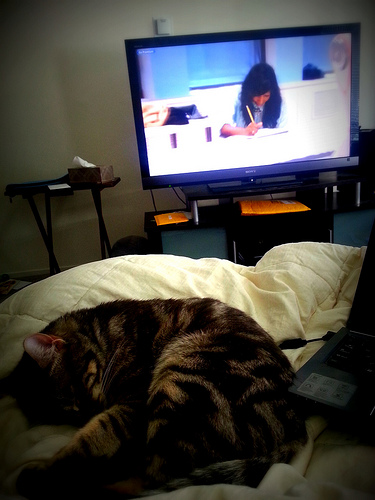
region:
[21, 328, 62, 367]
the ear of a cat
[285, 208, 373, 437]
a laptop on a bed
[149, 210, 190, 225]
an orange package on a table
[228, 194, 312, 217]
an orange package on a table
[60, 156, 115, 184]
a box of napkins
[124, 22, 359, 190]
a large black television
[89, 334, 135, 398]
a cat's white whisker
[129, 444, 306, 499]
the tail of a cat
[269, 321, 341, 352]
a laptop's power cable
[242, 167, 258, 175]
a SONY label on a television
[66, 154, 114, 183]
box of tissues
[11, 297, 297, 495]
a napping cat on a yellow blanket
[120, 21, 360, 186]
program on a television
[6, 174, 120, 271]
black tray table loaded with objects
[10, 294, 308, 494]
cat with black stripes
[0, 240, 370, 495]
yellow blankets with several things on top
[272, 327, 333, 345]
charge chord for a laptop computer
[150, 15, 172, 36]
thermostat on a wall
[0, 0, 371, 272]
white painted wall in a room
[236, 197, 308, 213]
manila envelope on a tv stand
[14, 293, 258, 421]
cat on the bed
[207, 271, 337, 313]
sheets of the bed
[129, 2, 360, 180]
tv on the stand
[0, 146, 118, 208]
small table next to tv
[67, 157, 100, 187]
tissue box on table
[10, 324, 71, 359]
ear of the cat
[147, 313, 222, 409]
stripes of the cat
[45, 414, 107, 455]
paw of the cat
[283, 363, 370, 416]
book on the bed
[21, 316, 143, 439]
the cat is curled up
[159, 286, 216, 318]
the cat is laying down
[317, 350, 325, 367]
the laptop is black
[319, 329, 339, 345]
the cord is plugged in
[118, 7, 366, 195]
A large black framed television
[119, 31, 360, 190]
A television turned on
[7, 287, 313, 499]
A sleeping cat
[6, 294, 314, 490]
A brown and black cat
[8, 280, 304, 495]
A cat curled up in a ball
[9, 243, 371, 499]
A beige colored comforter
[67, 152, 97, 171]
A white tissue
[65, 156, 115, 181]
A box of tissues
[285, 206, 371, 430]
A laptop computer